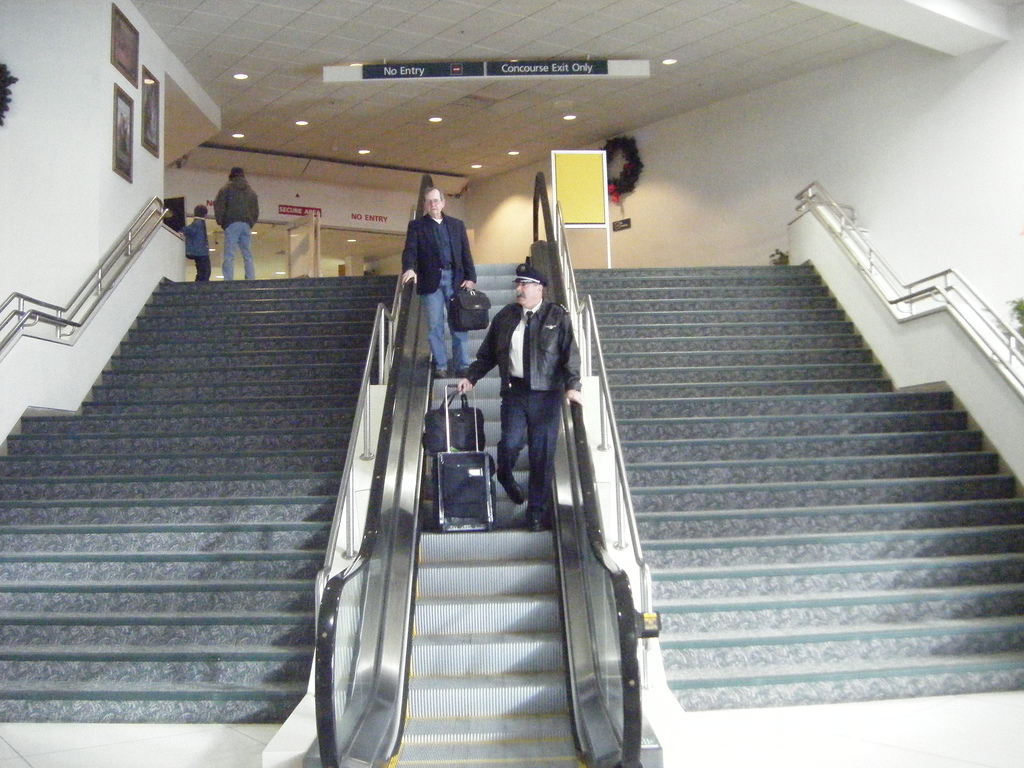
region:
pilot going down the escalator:
[427, 258, 590, 530]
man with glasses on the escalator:
[397, 180, 486, 376]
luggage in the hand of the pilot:
[418, 382, 491, 529]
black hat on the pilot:
[509, 262, 547, 289]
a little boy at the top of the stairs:
[179, 202, 215, 285]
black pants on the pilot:
[490, 379, 567, 528]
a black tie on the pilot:
[516, 310, 539, 387]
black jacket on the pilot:
[460, 298, 584, 397]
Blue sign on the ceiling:
[318, 57, 484, 86]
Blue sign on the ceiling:
[484, 56, 652, 77]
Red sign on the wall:
[273, 202, 322, 219]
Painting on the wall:
[108, 83, 137, 183]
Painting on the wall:
[108, 2, 140, 88]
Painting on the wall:
[138, 66, 162, 153]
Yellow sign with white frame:
[550, 145, 611, 267]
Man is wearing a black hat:
[510, 259, 548, 291]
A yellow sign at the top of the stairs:
[514, 104, 727, 321]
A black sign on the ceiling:
[279, 35, 729, 115]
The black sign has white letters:
[296, 12, 758, 149]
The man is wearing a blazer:
[371, 170, 518, 385]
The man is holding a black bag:
[389, 148, 506, 405]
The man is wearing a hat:
[465, 237, 611, 535]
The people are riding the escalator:
[301, 127, 731, 741]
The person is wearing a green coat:
[203, 149, 295, 309]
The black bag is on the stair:
[392, 363, 542, 554]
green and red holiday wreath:
[595, 136, 647, 206]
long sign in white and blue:
[317, 51, 656, 80]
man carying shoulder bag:
[403, 189, 495, 382]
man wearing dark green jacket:
[210, 165, 259, 279]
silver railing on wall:
[0, 1, 184, 438]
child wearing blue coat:
[181, 199, 214, 277]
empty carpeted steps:
[571, 256, 1021, 710]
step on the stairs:
[678, 672, 710, 702]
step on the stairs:
[829, 600, 871, 616]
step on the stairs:
[846, 560, 892, 581]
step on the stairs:
[858, 509, 888, 533]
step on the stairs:
[794, 486, 839, 506]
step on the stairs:
[174, 683, 267, 748]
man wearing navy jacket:
[398, 188, 498, 367]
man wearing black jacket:
[465, 262, 595, 523]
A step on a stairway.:
[638, 519, 1021, 576]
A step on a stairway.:
[0, 642, 317, 681]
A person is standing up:
[211, 165, 260, 282]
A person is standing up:
[454, 269, 585, 530]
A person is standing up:
[400, 182, 477, 379]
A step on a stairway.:
[610, 406, 968, 441]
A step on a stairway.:
[0, 468, 344, 501]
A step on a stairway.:
[100, 359, 367, 383]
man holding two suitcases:
[415, 253, 590, 551]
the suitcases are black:
[419, 372, 504, 545]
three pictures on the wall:
[99, 7, 175, 190]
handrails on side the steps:
[778, 167, 1021, 403]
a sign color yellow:
[534, 132, 629, 270]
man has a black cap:
[480, 247, 575, 344]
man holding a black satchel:
[392, 179, 501, 379]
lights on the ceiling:
[222, 70, 571, 165]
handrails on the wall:
[9, 184, 174, 392]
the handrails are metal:
[11, 194, 176, 357]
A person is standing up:
[489, 264, 579, 539]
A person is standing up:
[394, 181, 483, 382]